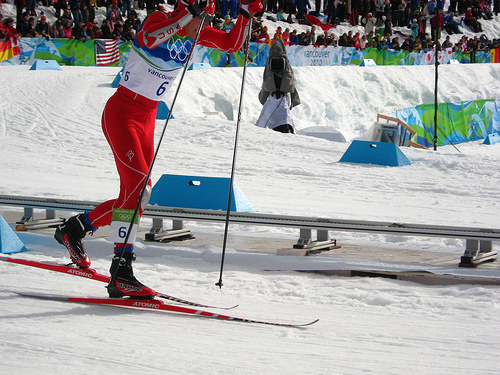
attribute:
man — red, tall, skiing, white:
[43, 8, 270, 265]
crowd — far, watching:
[4, 0, 499, 51]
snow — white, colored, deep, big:
[7, 67, 500, 374]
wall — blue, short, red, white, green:
[7, 38, 497, 79]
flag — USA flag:
[93, 30, 122, 72]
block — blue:
[340, 138, 407, 169]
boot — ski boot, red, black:
[106, 245, 157, 305]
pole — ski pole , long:
[211, 2, 256, 292]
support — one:
[294, 231, 317, 251]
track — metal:
[1, 197, 484, 268]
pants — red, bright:
[100, 87, 164, 222]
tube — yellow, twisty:
[403, 101, 484, 141]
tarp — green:
[416, 98, 482, 148]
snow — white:
[345, 284, 463, 371]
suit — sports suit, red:
[92, 8, 255, 247]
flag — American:
[87, 36, 123, 69]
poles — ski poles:
[132, 2, 255, 296]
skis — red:
[0, 248, 320, 335]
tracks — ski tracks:
[20, 81, 89, 161]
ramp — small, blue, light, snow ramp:
[333, 136, 408, 171]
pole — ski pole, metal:
[216, 19, 253, 293]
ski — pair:
[0, 256, 320, 331]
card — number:
[140, 68, 176, 106]